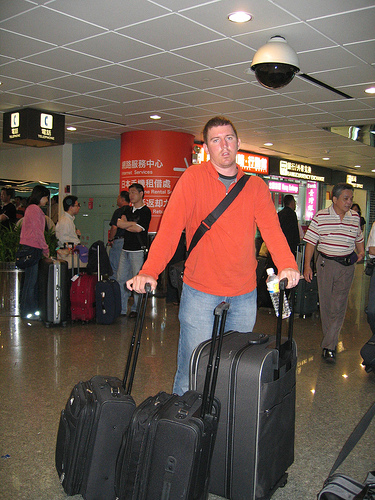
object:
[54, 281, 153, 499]
luggage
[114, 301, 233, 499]
luggage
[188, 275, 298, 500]
luggage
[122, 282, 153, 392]
handle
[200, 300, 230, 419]
handle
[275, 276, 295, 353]
handle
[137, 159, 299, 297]
sweatshirt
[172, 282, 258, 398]
jeans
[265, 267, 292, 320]
bottle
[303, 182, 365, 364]
man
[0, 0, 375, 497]
airport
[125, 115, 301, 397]
man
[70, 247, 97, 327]
suitcase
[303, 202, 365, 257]
shirt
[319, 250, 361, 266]
pouch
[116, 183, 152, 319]
man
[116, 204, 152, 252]
shirt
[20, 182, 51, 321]
lady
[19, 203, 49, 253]
sweater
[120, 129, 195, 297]
pillar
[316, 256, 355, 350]
pants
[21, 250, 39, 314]
jeans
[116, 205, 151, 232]
arms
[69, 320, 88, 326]
wheels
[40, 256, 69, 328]
luggage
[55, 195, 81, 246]
man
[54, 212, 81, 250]
shirt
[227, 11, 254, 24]
fixture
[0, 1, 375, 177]
ceiling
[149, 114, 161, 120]
fixture